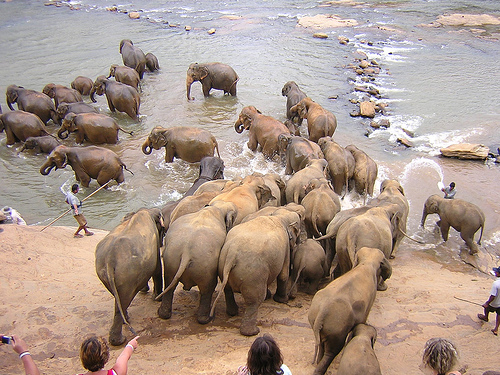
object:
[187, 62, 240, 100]
elephant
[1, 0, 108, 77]
water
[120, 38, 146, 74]
elephant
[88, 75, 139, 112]
elephant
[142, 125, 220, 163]
elephant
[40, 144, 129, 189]
elephant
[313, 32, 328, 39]
rock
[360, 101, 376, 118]
rock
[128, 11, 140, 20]
rock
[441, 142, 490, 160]
rock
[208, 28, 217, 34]
rock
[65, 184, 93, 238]
man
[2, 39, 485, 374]
elephants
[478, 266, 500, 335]
man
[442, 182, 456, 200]
man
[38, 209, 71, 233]
stick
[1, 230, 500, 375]
bank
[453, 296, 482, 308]
stick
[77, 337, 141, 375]
woman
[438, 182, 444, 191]
bucket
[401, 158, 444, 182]
water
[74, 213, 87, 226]
shorts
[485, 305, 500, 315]
shorts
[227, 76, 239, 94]
tail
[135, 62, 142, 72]
tail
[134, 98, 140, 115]
tail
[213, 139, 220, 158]
tail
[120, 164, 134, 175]
tail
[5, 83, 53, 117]
elephants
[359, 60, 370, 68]
rocks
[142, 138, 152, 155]
trunk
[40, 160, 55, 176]
trunk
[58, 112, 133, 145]
elephant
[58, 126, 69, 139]
trunk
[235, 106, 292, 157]
elephant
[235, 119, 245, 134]
trunk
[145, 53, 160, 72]
elephant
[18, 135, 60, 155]
elephant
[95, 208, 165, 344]
elephant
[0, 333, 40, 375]
person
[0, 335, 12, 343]
camera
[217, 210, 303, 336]
elephant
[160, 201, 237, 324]
elephant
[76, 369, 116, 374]
shirt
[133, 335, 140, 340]
finger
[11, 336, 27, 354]
hand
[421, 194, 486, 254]
elephant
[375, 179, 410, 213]
elephant